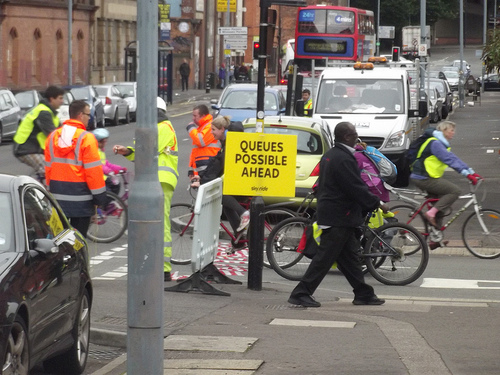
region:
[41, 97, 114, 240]
Man wearing an orange coat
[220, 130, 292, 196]
Yellow sign with black words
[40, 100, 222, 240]
Two men wearing orange coats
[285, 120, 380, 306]
Man wearing a black suit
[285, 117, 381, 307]
Man walking across the street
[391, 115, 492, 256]
Man on bike wearing red gloves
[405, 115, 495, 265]
Man riding a bicycle across the street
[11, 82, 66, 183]
Man wearing a hat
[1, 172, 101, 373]
Black car parked on the street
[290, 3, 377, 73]
Red and blue bus on the street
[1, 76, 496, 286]
A group of people in the foreground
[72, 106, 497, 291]
Group of people on bikes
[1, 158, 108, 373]
A sedan in the foreground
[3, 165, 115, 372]
The car is black in color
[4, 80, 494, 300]
People are using a crosswalk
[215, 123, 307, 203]
A yellow sign in the foreground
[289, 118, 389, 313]
A side view of a man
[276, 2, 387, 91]
A bus in the background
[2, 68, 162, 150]
A line of parked cars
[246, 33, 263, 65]
Traffic light is on red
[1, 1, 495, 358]
picture taken outside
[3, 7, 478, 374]
picture taken outdoors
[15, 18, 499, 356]
picture taken during the day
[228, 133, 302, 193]
a yellow sign says queues possible ahead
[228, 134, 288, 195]
the sign is yellow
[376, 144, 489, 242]
people are riding bikes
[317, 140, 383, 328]
a man is walking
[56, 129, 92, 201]
a man wears an orange coat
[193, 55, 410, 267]
a busy city street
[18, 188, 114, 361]
a car is parked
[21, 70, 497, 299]
several bikes on the street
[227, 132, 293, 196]
a sign with a yellow background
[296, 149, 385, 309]
a man dressed in black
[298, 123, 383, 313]
this man is walking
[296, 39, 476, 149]
many vehicles waiting to cross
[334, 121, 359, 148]
the head of the man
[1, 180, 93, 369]
a black car left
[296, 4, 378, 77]
a double decker bus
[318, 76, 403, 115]
the white truck windshields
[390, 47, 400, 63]
the red light